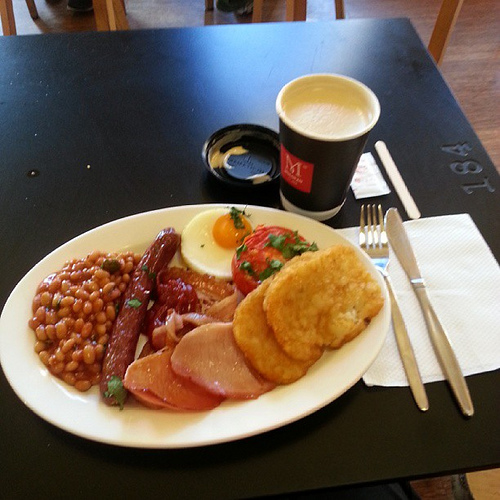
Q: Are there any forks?
A: Yes, there is a fork.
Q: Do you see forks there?
A: Yes, there is a fork.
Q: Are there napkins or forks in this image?
A: Yes, there is a fork.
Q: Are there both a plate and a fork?
A: Yes, there are both a fork and a plate.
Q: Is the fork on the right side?
A: Yes, the fork is on the right of the image.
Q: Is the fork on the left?
A: No, the fork is on the right of the image.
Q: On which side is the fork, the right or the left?
A: The fork is on the right of the image.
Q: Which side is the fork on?
A: The fork is on the right of the image.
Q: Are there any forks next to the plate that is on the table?
A: Yes, there is a fork next to the plate.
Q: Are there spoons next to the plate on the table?
A: No, there is a fork next to the plate.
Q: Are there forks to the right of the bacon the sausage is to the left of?
A: Yes, there is a fork to the right of the bacon.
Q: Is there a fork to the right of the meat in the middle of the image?
A: Yes, there is a fork to the right of the bacon.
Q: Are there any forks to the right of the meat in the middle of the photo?
A: Yes, there is a fork to the right of the bacon.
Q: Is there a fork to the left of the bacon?
A: No, the fork is to the right of the bacon.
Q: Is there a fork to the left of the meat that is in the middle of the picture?
A: No, the fork is to the right of the bacon.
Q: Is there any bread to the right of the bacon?
A: No, there is a fork to the right of the bacon.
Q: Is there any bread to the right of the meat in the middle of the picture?
A: No, there is a fork to the right of the bacon.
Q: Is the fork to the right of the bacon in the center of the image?
A: Yes, the fork is to the right of the bacon.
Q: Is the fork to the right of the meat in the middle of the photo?
A: Yes, the fork is to the right of the bacon.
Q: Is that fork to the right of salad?
A: No, the fork is to the right of the bacon.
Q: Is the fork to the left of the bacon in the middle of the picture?
A: No, the fork is to the right of the bacon.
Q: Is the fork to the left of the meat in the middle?
A: No, the fork is to the right of the bacon.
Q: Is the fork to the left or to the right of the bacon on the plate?
A: The fork is to the right of the bacon.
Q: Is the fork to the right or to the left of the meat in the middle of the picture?
A: The fork is to the right of the bacon.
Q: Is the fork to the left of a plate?
A: No, the fork is to the right of a plate.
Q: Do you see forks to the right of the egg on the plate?
A: Yes, there is a fork to the right of the egg.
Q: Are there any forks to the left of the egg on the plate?
A: No, the fork is to the right of the egg.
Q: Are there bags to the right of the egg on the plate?
A: No, there is a fork to the right of the egg.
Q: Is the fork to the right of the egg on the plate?
A: Yes, the fork is to the right of the egg.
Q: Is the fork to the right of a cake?
A: No, the fork is to the right of the egg.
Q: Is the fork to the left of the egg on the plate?
A: No, the fork is to the right of the egg.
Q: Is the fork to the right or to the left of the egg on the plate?
A: The fork is to the right of the egg.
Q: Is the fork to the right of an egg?
A: Yes, the fork is to the right of an egg.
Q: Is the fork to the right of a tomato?
A: No, the fork is to the right of an egg.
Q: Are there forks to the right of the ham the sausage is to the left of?
A: Yes, there is a fork to the right of the ham.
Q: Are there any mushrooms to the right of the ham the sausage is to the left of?
A: No, there is a fork to the right of the ham.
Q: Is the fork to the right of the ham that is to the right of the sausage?
A: Yes, the fork is to the right of the ham.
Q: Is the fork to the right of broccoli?
A: No, the fork is to the right of the ham.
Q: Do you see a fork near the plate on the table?
A: Yes, there is a fork near the plate.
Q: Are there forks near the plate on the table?
A: Yes, there is a fork near the plate.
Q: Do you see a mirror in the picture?
A: No, there are no mirrors.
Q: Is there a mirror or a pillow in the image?
A: No, there are no mirrors or pillows.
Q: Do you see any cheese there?
A: No, there is no cheese.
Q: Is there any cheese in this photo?
A: No, there is no cheese.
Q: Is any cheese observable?
A: No, there is no cheese.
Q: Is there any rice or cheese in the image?
A: No, there are no cheese or rice.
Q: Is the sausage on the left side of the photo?
A: Yes, the sausage is on the left of the image.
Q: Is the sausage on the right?
A: No, the sausage is on the left of the image.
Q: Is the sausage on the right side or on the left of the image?
A: The sausage is on the left of the image.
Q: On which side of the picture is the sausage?
A: The sausage is on the left of the image.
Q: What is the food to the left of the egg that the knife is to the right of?
A: The food is a sausage.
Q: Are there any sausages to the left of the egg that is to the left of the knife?
A: Yes, there is a sausage to the left of the egg.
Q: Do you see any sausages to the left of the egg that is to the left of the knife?
A: Yes, there is a sausage to the left of the egg.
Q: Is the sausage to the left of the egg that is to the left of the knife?
A: Yes, the sausage is to the left of the egg.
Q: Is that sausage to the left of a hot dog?
A: No, the sausage is to the left of the egg.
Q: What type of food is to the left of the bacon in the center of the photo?
A: The food is a sausage.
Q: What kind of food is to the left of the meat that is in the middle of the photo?
A: The food is a sausage.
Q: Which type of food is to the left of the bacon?
A: The food is a sausage.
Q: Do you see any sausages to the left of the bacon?
A: Yes, there is a sausage to the left of the bacon.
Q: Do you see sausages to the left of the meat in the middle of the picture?
A: Yes, there is a sausage to the left of the bacon.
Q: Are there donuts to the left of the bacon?
A: No, there is a sausage to the left of the bacon.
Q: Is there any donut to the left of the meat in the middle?
A: No, there is a sausage to the left of the bacon.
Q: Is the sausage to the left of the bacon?
A: Yes, the sausage is to the left of the bacon.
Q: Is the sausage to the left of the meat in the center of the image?
A: Yes, the sausage is to the left of the bacon.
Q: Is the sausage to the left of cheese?
A: No, the sausage is to the left of the bacon.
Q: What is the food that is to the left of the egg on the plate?
A: The food is a sausage.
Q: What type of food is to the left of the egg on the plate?
A: The food is a sausage.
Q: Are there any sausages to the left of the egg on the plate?
A: Yes, there is a sausage to the left of the egg.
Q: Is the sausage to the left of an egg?
A: Yes, the sausage is to the left of an egg.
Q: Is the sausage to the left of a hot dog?
A: No, the sausage is to the left of an egg.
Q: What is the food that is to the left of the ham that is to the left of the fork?
A: The food is a sausage.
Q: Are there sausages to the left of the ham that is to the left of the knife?
A: Yes, there is a sausage to the left of the ham.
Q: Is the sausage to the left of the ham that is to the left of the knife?
A: Yes, the sausage is to the left of the ham.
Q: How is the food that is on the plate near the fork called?
A: The food is a sausage.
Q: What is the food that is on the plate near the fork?
A: The food is a sausage.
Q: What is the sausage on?
A: The sausage is on the plate.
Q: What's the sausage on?
A: The sausage is on the plate.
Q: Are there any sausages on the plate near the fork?
A: Yes, there is a sausage on the plate.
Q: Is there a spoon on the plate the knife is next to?
A: No, there is a sausage on the plate.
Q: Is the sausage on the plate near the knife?
A: Yes, the sausage is on the plate.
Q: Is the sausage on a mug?
A: No, the sausage is on the plate.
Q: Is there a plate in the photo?
A: Yes, there is a plate.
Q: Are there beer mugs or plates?
A: Yes, there is a plate.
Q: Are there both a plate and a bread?
A: No, there is a plate but no breads.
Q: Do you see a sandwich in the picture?
A: No, there are no sandwiches.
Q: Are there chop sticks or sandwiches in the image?
A: No, there are no sandwiches or chop sticks.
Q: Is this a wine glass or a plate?
A: This is a plate.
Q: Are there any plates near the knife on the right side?
A: Yes, there is a plate near the knife.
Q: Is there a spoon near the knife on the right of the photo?
A: No, there is a plate near the knife.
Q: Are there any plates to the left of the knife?
A: Yes, there is a plate to the left of the knife.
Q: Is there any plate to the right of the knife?
A: No, the plate is to the left of the knife.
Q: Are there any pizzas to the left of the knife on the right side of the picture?
A: No, there is a plate to the left of the knife.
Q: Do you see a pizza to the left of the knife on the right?
A: No, there is a plate to the left of the knife.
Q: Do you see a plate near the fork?
A: Yes, there is a plate near the fork.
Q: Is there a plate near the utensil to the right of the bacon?
A: Yes, there is a plate near the fork.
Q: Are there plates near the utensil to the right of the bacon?
A: Yes, there is a plate near the fork.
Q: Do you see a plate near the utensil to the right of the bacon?
A: Yes, there is a plate near the fork.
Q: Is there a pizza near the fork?
A: No, there is a plate near the fork.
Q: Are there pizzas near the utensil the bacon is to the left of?
A: No, there is a plate near the fork.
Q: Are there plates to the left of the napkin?
A: Yes, there is a plate to the left of the napkin.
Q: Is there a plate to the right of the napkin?
A: No, the plate is to the left of the napkin.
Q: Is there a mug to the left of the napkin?
A: No, there is a plate to the left of the napkin.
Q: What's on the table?
A: The plate is on the table.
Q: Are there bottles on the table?
A: No, there is a plate on the table.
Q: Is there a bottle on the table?
A: No, there is a plate on the table.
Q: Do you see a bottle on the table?
A: No, there is a plate on the table.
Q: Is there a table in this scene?
A: Yes, there is a table.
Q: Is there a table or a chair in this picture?
A: Yes, there is a table.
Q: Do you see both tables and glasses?
A: No, there is a table but no glasses.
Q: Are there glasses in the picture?
A: No, there are no glasses.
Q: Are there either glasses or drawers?
A: No, there are no glasses or drawers.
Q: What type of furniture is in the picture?
A: The furniture is a table.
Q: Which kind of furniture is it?
A: The piece of furniture is a table.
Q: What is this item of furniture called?
A: This is a table.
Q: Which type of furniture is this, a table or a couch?
A: This is a table.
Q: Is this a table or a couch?
A: This is a table.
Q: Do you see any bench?
A: No, there are no benches.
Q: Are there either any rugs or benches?
A: No, there are no benches or rugs.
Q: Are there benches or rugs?
A: No, there are no benches or rugs.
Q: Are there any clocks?
A: No, there are no clocks.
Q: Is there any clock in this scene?
A: No, there are no clocks.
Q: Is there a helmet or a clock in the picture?
A: No, there are no clocks or helmets.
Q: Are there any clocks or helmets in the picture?
A: No, there are no clocks or helmets.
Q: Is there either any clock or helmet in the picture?
A: No, there are no clocks or helmets.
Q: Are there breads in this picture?
A: No, there are no breads.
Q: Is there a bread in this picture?
A: No, there is no breads.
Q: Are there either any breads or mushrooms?
A: No, there are no breads or mushrooms.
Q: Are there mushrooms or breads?
A: No, there are no breads or mushrooms.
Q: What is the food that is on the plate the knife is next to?
A: The food is an egg.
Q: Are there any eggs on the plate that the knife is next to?
A: Yes, there is an egg on the plate.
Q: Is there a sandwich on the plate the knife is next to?
A: No, there is an egg on the plate.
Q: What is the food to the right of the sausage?
A: The food is an egg.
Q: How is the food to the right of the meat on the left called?
A: The food is an egg.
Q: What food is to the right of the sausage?
A: The food is an egg.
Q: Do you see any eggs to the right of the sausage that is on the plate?
A: Yes, there is an egg to the right of the sausage.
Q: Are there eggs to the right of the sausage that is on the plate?
A: Yes, there is an egg to the right of the sausage.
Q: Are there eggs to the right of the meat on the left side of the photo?
A: Yes, there is an egg to the right of the sausage.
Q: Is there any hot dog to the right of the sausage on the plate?
A: No, there is an egg to the right of the sausage.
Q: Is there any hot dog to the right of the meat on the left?
A: No, there is an egg to the right of the sausage.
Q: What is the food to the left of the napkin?
A: The food is an egg.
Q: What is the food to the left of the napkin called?
A: The food is an egg.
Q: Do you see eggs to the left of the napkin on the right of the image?
A: Yes, there is an egg to the left of the napkin.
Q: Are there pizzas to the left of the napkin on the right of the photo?
A: No, there is an egg to the left of the napkin.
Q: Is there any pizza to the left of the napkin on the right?
A: No, there is an egg to the left of the napkin.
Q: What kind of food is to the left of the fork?
A: The food is an egg.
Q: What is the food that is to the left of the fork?
A: The food is an egg.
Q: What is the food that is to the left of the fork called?
A: The food is an egg.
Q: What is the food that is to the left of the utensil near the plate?
A: The food is an egg.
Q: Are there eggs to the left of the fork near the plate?
A: Yes, there is an egg to the left of the fork.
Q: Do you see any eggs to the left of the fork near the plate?
A: Yes, there is an egg to the left of the fork.